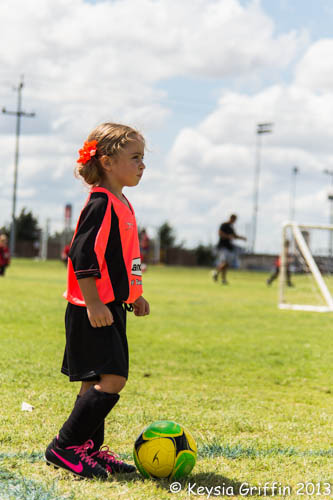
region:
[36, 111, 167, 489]
this is a girl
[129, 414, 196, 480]
this is a football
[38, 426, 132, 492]
these are sneakers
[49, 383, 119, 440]
these are black socks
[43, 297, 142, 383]
the girl is wearing black shorts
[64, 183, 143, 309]
the shirt is orange and black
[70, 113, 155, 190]
the hair is blonde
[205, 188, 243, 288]
this is a person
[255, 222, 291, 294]
this is a person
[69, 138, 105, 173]
the girl has a flower on her hair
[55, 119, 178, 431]
girl on soccer field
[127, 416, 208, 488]
soccer ball on grass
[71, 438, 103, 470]
pink laces on shoes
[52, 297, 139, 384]
black shorts on girl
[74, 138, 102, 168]
orange flower in hair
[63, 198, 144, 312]
orange and black shirt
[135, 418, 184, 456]
green, black and yellow on ball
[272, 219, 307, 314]
white post of goal net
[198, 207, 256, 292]
adult on soccer field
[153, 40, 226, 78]
white clouds in sky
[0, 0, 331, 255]
blue cloudy sky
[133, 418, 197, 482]
green yellow and black soccer ball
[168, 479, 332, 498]
photographers watermark and date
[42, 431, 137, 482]
pink and black soccer cleats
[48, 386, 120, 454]
little girls black shin guards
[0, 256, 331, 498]
green grass soccer field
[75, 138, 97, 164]
orange flower hair bow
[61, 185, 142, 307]
orange and black soccer jersey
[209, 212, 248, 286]
adult male coach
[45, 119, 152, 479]
little girl soccer player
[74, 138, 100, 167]
Orange flower in little gir's hair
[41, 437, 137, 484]
Pink Nike soccer cleats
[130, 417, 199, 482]
Green, yellow and black soccer ball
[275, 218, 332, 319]
White soccer goal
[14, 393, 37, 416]
Trash on the soccer field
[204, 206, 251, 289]
Coach teaching a player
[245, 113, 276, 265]
Stadium lights for night visibility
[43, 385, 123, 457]
Black shin guards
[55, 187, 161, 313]
Orange and black soccer jersey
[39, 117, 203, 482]
Little girl playing soccer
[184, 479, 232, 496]
keysia is in white letterings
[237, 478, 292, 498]
griffin is in white letterings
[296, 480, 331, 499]
2013 in white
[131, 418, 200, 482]
a soccer ball on field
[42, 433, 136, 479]
pink and black kleats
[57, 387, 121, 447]
black socks on player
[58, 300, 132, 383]
black shorts on player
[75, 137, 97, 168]
bow tie in hair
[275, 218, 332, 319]
a goalie on field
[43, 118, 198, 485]
a girl on field with ball